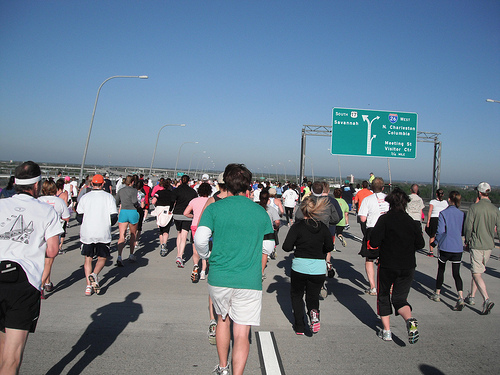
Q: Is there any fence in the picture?
A: No, there are no fences.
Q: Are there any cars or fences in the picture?
A: No, there are no fences or cars.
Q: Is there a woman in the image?
A: Yes, there is a woman.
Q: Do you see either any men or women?
A: Yes, there is a woman.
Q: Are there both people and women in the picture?
A: Yes, there are both a woman and people.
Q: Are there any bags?
A: No, there are no bags.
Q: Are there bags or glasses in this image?
A: No, there are no bags or glasses.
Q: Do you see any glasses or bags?
A: No, there are no bags or glasses.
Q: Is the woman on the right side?
A: Yes, the woman is on the right of the image.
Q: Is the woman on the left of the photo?
A: No, the woman is on the right of the image.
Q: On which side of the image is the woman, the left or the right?
A: The woman is on the right of the image.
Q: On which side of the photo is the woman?
A: The woman is on the right of the image.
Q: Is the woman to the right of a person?
A: Yes, the woman is to the right of a person.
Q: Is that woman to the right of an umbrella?
A: No, the woman is to the right of a person.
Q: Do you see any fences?
A: No, there are no fences.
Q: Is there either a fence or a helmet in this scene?
A: No, there are no fences or helmets.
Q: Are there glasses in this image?
A: No, there are no glasses.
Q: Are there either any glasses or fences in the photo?
A: No, there are no glasses or fences.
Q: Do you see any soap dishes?
A: No, there are no soap dishes.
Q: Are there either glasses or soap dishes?
A: No, there are no soap dishes or glasses.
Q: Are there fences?
A: No, there are no fences.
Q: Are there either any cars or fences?
A: No, there are no fences or cars.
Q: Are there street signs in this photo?
A: Yes, there is a street sign.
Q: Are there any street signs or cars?
A: Yes, there is a street sign.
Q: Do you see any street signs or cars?
A: Yes, there is a street sign.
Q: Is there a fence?
A: No, there are no fences.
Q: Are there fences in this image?
A: No, there are no fences.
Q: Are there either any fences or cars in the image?
A: No, there are no fences or cars.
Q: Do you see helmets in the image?
A: No, there are no helmets.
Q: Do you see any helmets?
A: No, there are no helmets.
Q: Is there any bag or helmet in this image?
A: No, there are no helmets or bags.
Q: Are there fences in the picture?
A: No, there are no fences.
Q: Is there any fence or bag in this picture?
A: No, there are no fences or bags.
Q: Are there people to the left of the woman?
A: Yes, there is a person to the left of the woman.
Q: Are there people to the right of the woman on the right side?
A: No, the person is to the left of the woman.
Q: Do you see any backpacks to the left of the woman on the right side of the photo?
A: No, there is a person to the left of the woman.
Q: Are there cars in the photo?
A: No, there are no cars.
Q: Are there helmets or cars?
A: No, there are no cars or helmets.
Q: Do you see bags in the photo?
A: No, there are no bags.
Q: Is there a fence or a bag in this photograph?
A: No, there are no bags or fences.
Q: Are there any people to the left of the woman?
A: Yes, there is a person to the left of the woman.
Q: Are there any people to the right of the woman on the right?
A: No, the person is to the left of the woman.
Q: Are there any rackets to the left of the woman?
A: No, there is a person to the left of the woman.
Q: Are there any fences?
A: No, there are no fences.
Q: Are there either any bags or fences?
A: No, there are no fences or bags.